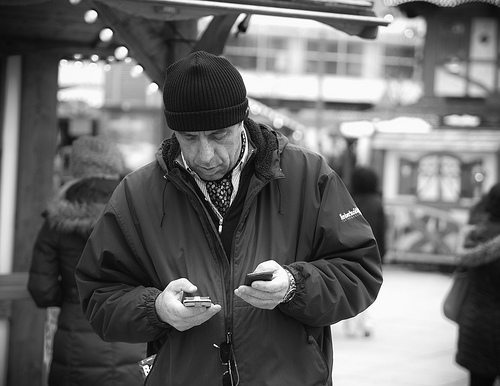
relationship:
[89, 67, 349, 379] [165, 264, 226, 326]
man checking phone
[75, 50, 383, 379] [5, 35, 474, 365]
man sending message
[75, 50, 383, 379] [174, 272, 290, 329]
man holding phones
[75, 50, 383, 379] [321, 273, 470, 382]
man on sidewalk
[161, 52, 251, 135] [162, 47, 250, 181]
hat on head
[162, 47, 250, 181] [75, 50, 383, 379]
head of man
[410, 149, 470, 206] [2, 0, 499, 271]
windows on building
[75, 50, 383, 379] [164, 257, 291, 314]
man holding phones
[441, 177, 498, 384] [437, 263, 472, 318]
person carrying bag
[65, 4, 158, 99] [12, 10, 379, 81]
lights on awning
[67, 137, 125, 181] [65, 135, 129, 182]
bonnet on head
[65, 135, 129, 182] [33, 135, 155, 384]
head of person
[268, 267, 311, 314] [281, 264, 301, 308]
watch on wrist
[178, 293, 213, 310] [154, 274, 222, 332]
object in hands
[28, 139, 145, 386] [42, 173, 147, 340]
person wearing jacket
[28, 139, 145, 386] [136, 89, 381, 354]
person behind man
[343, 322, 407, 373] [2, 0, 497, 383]
ground in photo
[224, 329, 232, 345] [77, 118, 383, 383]
zipper on jacket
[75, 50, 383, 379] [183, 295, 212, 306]
man checking cell phone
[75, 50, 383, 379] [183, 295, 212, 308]
man using cell phone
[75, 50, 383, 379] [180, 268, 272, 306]
man checking messages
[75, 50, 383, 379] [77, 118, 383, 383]
man wearing jacket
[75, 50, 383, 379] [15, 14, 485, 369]
man in city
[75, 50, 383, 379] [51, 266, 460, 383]
man on sidewalk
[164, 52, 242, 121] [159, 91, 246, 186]
hat on head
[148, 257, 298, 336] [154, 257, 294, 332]
cell phones are in hands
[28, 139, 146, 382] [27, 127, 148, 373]
person wearing jacket